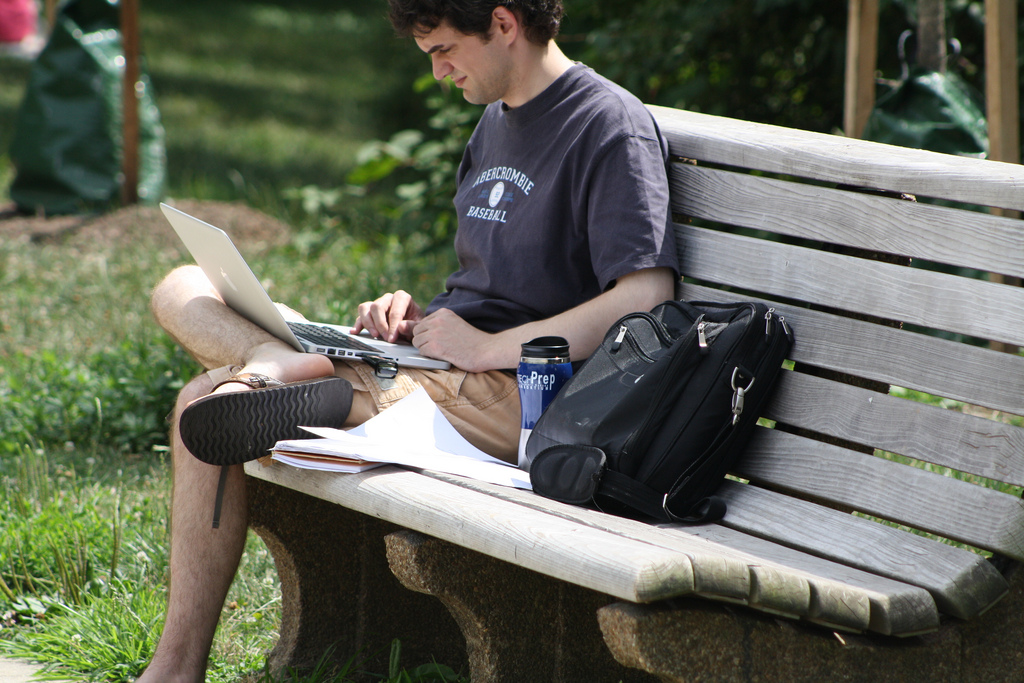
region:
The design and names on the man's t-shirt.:
[452, 150, 538, 221]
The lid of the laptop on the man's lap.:
[159, 207, 289, 343]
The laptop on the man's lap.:
[156, 201, 450, 375]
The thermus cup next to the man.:
[513, 334, 567, 449]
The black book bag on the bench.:
[528, 294, 798, 523]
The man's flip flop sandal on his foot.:
[177, 368, 348, 468]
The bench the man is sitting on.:
[168, 119, 1017, 676]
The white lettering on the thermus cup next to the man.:
[507, 371, 555, 392]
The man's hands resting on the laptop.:
[352, 277, 502, 372]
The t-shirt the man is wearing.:
[450, 76, 678, 298]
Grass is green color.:
[16, 355, 131, 681]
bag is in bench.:
[550, 298, 750, 521]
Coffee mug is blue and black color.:
[493, 327, 591, 492]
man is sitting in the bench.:
[170, 30, 674, 613]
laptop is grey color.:
[171, 172, 431, 379]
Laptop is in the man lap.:
[152, 182, 440, 427]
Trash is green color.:
[15, 14, 183, 256]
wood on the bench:
[835, 146, 947, 195]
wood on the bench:
[855, 187, 916, 252]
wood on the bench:
[832, 386, 884, 457]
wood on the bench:
[879, 500, 902, 516]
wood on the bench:
[848, 569, 903, 617]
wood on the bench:
[541, 534, 655, 589]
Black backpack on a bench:
[529, 297, 804, 519]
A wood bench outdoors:
[243, 98, 1015, 672]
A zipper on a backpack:
[610, 314, 650, 365]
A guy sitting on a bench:
[139, 0, 674, 675]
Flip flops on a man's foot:
[177, 365, 355, 470]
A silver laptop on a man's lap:
[163, 197, 452, 374]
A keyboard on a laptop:
[283, 314, 375, 363]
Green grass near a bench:
[8, 197, 442, 679]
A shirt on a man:
[441, 61, 689, 330]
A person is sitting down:
[129, 0, 680, 680]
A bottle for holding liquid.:
[520, 333, 574, 471]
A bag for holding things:
[524, 298, 797, 520]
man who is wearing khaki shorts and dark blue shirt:
[117, 0, 690, 679]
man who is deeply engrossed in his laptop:
[120, 0, 693, 679]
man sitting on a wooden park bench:
[127, 2, 685, 679]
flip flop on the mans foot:
[174, 368, 356, 470]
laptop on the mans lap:
[155, 201, 459, 376]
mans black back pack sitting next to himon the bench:
[515, 290, 804, 531]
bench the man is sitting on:
[224, 100, 1021, 679]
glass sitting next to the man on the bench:
[505, 331, 579, 472]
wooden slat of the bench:
[639, 99, 1020, 211]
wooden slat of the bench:
[668, 153, 1020, 289]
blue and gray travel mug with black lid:
[512, 331, 569, 474]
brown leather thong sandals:
[176, 372, 358, 467]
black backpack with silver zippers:
[519, 290, 795, 522]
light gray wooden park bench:
[200, 93, 1022, 679]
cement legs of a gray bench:
[189, 464, 1021, 679]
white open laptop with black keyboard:
[158, 200, 452, 377]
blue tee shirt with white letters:
[427, 61, 690, 393]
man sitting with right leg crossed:
[120, 2, 687, 679]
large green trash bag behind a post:
[4, 3, 170, 222]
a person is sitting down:
[115, 5, 679, 679]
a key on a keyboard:
[285, 317, 296, 325]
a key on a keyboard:
[303, 323, 314, 328]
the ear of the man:
[485, 11, 518, 41]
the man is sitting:
[117, 1, 678, 665]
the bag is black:
[513, 288, 796, 529]